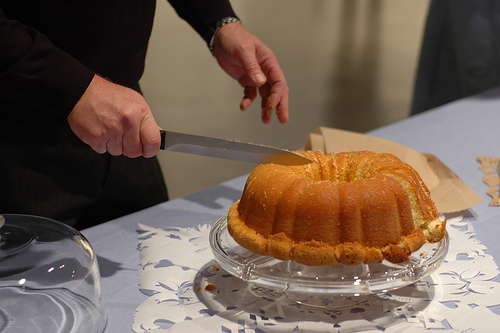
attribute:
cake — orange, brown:
[234, 135, 431, 271]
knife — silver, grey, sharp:
[154, 116, 299, 180]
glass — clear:
[227, 240, 455, 311]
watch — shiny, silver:
[214, 15, 243, 29]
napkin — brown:
[318, 123, 450, 194]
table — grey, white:
[347, 87, 495, 259]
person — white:
[4, 1, 268, 189]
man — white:
[1, 4, 296, 161]